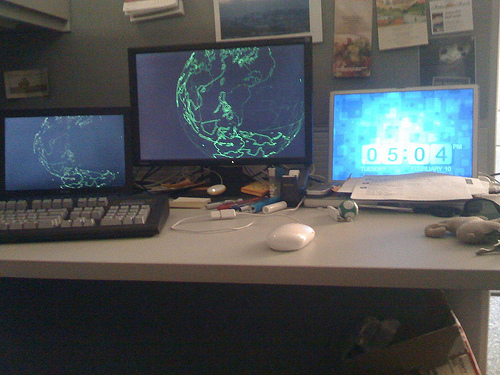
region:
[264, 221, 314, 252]
white mouse on the desk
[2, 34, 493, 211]
row of three monitors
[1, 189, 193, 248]
large black keyboard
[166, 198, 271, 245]
thin white wire laying on the desk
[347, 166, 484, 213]
thin sheet of paper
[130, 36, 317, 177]
monitor is turned on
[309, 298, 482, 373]
box under the desk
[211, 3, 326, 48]
picture hanging on the wall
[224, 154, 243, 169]
tiny light o the monitor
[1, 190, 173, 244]
gray keys on the black keyboard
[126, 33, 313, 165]
black computer monitor displaying a green globe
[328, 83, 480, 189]
white computer monitor displaying a digital clock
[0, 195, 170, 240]
black and white keyboard in an office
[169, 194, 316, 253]
white computer mouse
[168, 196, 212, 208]
yellow post-it notes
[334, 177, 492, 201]
pieces of paper with printing on them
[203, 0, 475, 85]
pictures on up on a cubicle wall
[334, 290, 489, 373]
box under a desk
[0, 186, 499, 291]
white desk in an office cubicle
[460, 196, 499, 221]
sunglasses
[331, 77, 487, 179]
white computer monitor on desk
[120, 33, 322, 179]
black computer monitor on desk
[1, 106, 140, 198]
black computer monitor on desk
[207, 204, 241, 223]
small bottle of white out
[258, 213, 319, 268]
white computer mouse on a desk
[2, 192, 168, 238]
blak keyboard with gray keys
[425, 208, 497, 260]
stuffed elephant sitting on a desk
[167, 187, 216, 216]
pad of yellow post it notes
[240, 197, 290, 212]
blue highlighter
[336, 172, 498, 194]
white keyboard to computer sitting on desk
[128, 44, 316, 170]
image on a computer monitor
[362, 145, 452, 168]
a time is on the screen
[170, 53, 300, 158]
black and green representation of earth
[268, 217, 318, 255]
white cordless mouse on desk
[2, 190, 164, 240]
black keyboard with grey keys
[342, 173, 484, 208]
small stack of papers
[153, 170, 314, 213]
miscellaneous junk under monitor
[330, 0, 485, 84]
papers posted on bulletin board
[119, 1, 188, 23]
the bottom of a white calendar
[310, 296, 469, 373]
cardboard box under desk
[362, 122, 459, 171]
the time showing on a computer screen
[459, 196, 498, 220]
pair of sunglasses laying on the desk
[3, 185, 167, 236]
keyboard with light grey keys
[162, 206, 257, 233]
white cord laying on the desk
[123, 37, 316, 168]
computer monitor with an outline of the earth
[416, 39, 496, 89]
picture tacked to the wall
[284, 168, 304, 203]
tape dispenser on the desk under the monitor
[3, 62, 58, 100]
bent paper on the wall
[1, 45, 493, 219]
three computer monitors on the desk